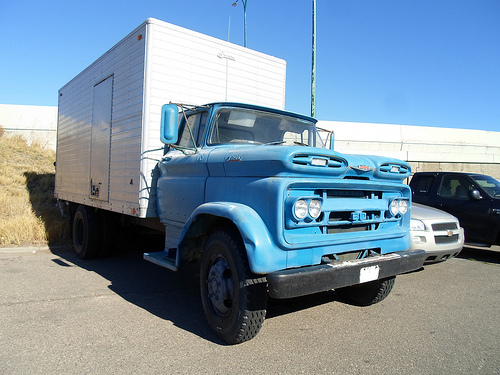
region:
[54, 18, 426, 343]
light blue truck parked in the parking lot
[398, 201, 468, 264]
silver car parked next to the blue truck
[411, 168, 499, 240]
black car parked in the lot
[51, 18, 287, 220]
white container on the back of the blue truck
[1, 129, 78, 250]
patch of dead grass behind the truck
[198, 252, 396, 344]
front tires on the blue truck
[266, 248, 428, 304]
front bumpers on the blue truck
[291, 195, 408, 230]
front headlights on the blue truck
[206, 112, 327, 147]
front windshield on the truck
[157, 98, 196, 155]
passenger side mirror on the truck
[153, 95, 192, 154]
Right window of big truck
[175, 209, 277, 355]
Right tire of blue truck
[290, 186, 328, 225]
Right headlight of blue truck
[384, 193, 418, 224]
Left headlight of blue truck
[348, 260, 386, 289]
front license plate on black bumper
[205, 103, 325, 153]
Front windshield of blue truck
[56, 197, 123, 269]
Rear wheels of blue truck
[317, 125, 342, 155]
Left mirror on blue truck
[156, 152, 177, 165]
Right handle on blue door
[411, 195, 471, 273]
Front of silver parked car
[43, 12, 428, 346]
truck is blue in front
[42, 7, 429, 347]
turck has white in back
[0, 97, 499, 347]
white wall behind trucks and car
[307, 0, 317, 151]
pole is green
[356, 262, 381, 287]
license plate is white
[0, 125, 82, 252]
grass on ground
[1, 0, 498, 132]
sky is blue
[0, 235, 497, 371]
road is gray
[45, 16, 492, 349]
gray car in middle of pick up truck and truck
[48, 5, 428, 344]
truck has black tires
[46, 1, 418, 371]
a blue and white truck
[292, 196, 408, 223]
head lights on a truck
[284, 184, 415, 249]
the front end of a blue truck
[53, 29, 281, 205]
a box bed on back of truck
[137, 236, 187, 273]
a blue step on truck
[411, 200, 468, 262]
a white car parked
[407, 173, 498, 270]
a black truck parked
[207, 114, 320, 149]
the windshield of a truck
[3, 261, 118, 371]
a gray prking lot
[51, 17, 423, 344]
A truck is parked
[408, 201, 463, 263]
A car is parked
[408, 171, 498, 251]
Blue truck is parked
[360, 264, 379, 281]
License plate is white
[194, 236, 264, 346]
The tire is black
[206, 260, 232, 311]
The hub cap is blue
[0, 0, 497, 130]
Sky is clear and blue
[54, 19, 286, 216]
The trailer is white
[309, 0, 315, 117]
A tall green pole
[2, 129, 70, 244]
Hill with dead grass